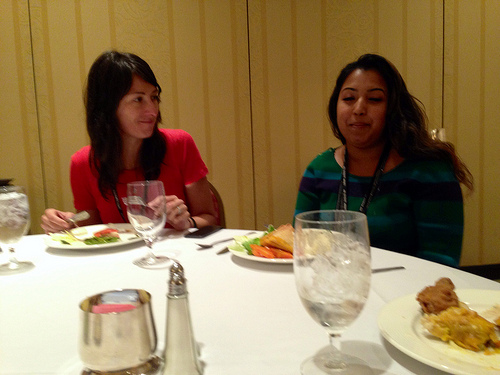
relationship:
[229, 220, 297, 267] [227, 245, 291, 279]
food on plate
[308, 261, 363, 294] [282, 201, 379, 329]
ice in glass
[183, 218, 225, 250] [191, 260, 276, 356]
phone on table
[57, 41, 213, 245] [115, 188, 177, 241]
girl holding fork